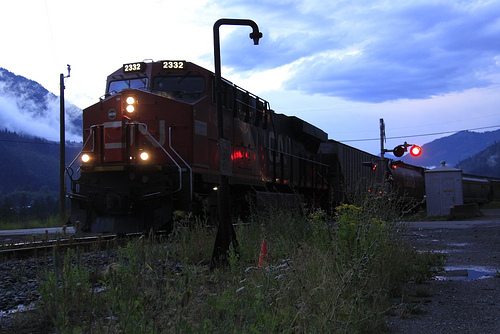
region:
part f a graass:
[256, 238, 278, 270]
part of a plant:
[298, 288, 322, 318]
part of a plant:
[337, 208, 352, 234]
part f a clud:
[376, 62, 432, 145]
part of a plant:
[313, 250, 337, 294]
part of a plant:
[314, 233, 339, 277]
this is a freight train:
[68, 28, 498, 263]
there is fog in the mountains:
[9, 56, 92, 154]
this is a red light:
[387, 132, 434, 172]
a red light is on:
[392, 106, 451, 184]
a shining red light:
[391, 128, 441, 161]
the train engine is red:
[86, 45, 267, 235]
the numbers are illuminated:
[113, 47, 203, 79]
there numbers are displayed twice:
[111, 52, 201, 77]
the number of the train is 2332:
[156, 55, 198, 73]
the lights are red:
[386, 134, 427, 170]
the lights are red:
[376, 134, 446, 181]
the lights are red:
[386, 141, 439, 166]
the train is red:
[61, 48, 338, 234]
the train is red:
[60, 48, 318, 213]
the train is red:
[59, 44, 287, 208]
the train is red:
[57, 34, 297, 216]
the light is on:
[408, 140, 422, 159]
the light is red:
[407, 143, 422, 156]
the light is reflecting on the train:
[231, 145, 252, 166]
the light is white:
[124, 94, 136, 112]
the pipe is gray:
[160, 146, 177, 167]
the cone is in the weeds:
[251, 228, 269, 273]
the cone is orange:
[253, 233, 274, 268]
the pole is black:
[211, 95, 227, 130]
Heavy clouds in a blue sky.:
[299, 21, 499, 88]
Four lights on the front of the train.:
[77, 93, 164, 169]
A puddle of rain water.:
[442, 255, 498, 290]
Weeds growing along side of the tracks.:
[64, 222, 394, 330]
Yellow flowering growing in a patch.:
[302, 195, 383, 258]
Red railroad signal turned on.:
[377, 117, 422, 243]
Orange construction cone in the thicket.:
[254, 232, 276, 278]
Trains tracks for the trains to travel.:
[0, 225, 140, 282]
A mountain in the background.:
[397, 124, 499, 175]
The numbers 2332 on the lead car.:
[123, 50, 186, 72]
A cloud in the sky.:
[320, 63, 405, 115]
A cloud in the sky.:
[401, 62, 428, 82]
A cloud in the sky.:
[429, 40, 459, 60]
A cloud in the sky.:
[203, 10, 477, 122]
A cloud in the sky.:
[7, 82, 131, 157]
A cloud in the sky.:
[45, 104, 77, 131]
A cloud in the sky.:
[15, 107, 45, 135]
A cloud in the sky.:
[277, 39, 323, 74]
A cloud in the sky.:
[378, 32, 440, 59]